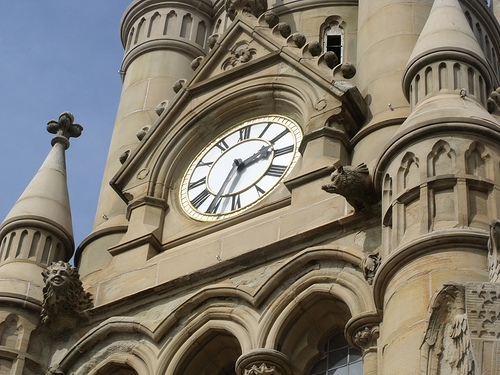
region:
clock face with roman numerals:
[156, 76, 335, 248]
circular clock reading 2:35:
[151, 96, 345, 234]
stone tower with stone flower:
[7, 99, 87, 265]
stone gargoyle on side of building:
[31, 257, 102, 329]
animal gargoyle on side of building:
[321, 149, 381, 221]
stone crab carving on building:
[217, 28, 272, 73]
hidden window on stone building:
[313, 9, 353, 63]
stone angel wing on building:
[418, 274, 469, 373]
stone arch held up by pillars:
[235, 240, 384, 347]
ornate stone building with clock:
[21, 11, 476, 357]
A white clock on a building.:
[173, 107, 305, 232]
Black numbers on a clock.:
[234, 120, 255, 143]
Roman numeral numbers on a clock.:
[267, 161, 287, 180]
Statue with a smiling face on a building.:
[33, 253, 98, 329]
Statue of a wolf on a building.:
[316, 158, 381, 218]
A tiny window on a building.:
[319, 18, 349, 67]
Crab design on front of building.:
[208, 34, 267, 74]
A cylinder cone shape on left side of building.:
[3, 102, 85, 251]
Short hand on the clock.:
[241, 134, 274, 174]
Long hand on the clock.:
[199, 156, 245, 218]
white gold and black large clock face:
[182, 120, 299, 212]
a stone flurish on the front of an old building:
[117, 147, 132, 162]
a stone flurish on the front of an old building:
[134, 123, 149, 134]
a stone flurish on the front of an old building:
[155, 99, 169, 113]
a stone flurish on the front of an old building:
[42, 106, 79, 140]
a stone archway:
[262, 256, 372, 361]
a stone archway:
[160, 288, 257, 373]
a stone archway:
[58, 323, 155, 372]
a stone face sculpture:
[41, 261, 95, 317]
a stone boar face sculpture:
[319, 164, 369, 209]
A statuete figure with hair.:
[40, 258, 90, 329]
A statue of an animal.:
[311, 153, 378, 214]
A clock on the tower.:
[177, 109, 309, 221]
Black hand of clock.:
[227, 145, 273, 165]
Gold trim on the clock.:
[176, 111, 304, 231]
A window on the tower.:
[329, 348, 358, 373]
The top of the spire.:
[40, 105, 86, 150]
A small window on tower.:
[321, 17, 344, 64]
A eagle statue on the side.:
[416, 216, 497, 374]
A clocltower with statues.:
[30, 0, 498, 372]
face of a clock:
[167, 109, 307, 224]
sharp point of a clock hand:
[269, 141, 274, 150]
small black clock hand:
[237, 144, 273, 165]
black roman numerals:
[236, 126, 256, 143]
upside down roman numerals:
[228, 192, 242, 214]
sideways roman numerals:
[271, 142, 294, 159]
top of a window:
[301, 333, 361, 374]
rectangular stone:
[155, 241, 222, 282]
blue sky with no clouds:
[1, 1, 129, 266]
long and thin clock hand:
[203, 161, 235, 218]